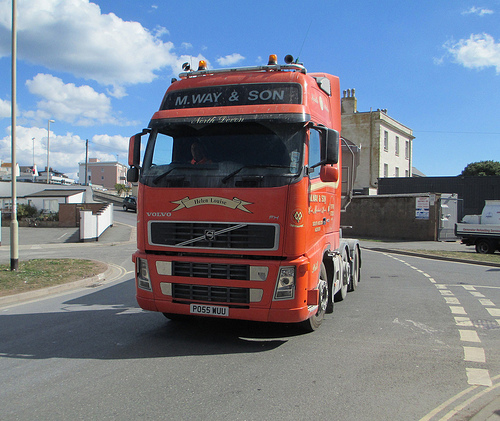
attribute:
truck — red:
[126, 62, 359, 329]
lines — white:
[371, 247, 499, 385]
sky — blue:
[0, 1, 499, 175]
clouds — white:
[1, 0, 168, 95]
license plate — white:
[189, 305, 230, 316]